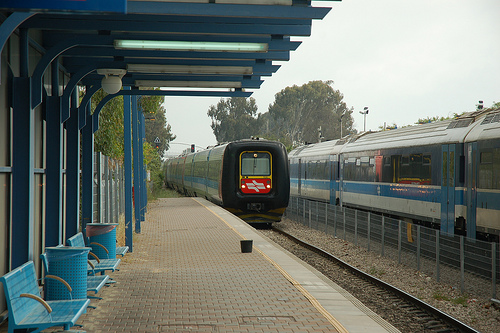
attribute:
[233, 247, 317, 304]
line — yellow, caution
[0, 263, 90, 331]
bench — blue, metal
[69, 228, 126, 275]
bench — blue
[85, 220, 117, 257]
garbage can — metal, blue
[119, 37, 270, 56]
tube — llluminated, long, light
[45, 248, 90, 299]
can — next to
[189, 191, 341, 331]
line — yellow 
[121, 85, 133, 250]
pole — blue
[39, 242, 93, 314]
trashcan — blue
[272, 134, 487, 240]
train — white and blue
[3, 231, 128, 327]
benches — Blue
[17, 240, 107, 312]
handles — brown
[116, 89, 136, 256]
pole — Blue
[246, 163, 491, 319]
fence — metal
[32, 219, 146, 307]
bench — blue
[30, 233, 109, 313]
can — blue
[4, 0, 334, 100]
overhang — blue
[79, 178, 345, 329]
sidewalk — brick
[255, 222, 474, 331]
train track — standard-width